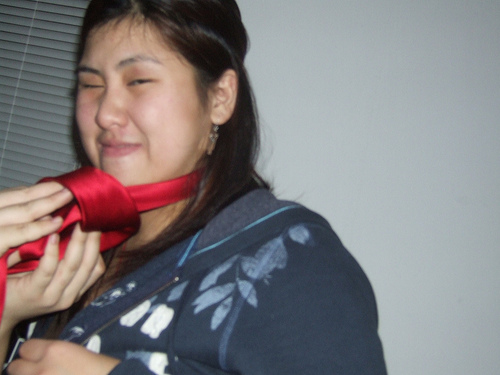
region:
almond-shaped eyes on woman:
[66, 57, 211, 103]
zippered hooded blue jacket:
[91, 221, 412, 355]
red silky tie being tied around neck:
[11, 157, 221, 275]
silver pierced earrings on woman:
[206, 117, 236, 158]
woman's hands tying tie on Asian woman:
[2, 182, 117, 318]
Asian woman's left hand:
[0, 329, 128, 370]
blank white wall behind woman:
[268, 30, 462, 227]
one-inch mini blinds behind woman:
[0, 23, 63, 160]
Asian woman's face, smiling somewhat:
[66, 34, 191, 184]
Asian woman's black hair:
[152, 12, 295, 195]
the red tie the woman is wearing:
[7, 145, 193, 295]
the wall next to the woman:
[244, 2, 499, 371]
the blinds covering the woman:
[1, 0, 83, 190]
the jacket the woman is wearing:
[39, 186, 383, 366]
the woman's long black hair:
[63, 2, 279, 308]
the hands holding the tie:
[4, 178, 120, 313]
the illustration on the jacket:
[92, 231, 298, 373]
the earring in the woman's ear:
[201, 121, 223, 152]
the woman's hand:
[9, 327, 86, 374]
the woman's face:
[58, 26, 195, 199]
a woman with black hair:
[14, 6, 276, 189]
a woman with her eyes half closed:
[46, 3, 268, 150]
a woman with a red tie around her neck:
[45, 1, 261, 238]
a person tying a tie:
[0, 160, 144, 327]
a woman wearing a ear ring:
[105, 50, 239, 207]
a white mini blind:
[0, 0, 87, 169]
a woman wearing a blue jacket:
[104, 110, 314, 372]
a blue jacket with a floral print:
[166, 162, 334, 364]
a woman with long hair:
[19, 11, 262, 261]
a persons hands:
[1, 155, 97, 363]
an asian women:
[49, 10, 389, 372]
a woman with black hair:
[27, 21, 354, 260]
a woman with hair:
[42, 15, 332, 345]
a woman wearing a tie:
[32, 27, 424, 360]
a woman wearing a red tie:
[12, 52, 335, 314]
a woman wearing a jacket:
[4, 37, 401, 372]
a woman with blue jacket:
[23, 61, 408, 338]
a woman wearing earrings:
[1, 1, 401, 246]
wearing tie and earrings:
[42, 42, 349, 245]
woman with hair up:
[22, 24, 389, 371]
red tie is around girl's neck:
[17, 154, 228, 284]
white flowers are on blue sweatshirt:
[192, 243, 294, 323]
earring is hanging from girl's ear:
[199, 73, 242, 160]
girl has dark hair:
[73, 1, 280, 255]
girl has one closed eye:
[68, 67, 113, 102]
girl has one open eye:
[120, 56, 172, 103]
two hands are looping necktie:
[1, 161, 149, 313]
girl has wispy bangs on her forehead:
[89, 8, 184, 55]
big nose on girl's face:
[83, 85, 135, 140]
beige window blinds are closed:
[2, 0, 74, 192]